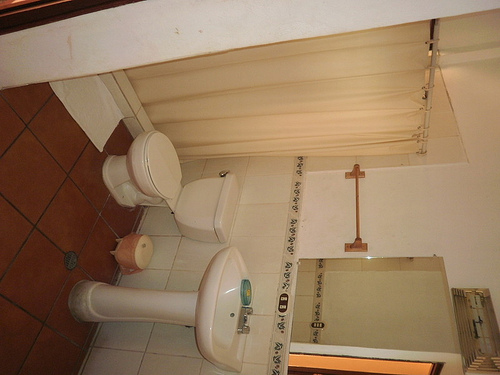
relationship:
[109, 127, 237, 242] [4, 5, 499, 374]
toilet in bathroom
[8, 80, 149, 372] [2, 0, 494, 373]
tiled floor of room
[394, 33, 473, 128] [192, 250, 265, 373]
light above sink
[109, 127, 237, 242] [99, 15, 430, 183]
toilet by shower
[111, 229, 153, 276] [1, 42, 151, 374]
basket on floor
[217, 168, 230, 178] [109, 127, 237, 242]
handle of toilet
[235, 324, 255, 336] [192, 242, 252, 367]
handle of sink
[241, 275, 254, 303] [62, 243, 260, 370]
item on sink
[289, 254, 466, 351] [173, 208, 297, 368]
mirror above sink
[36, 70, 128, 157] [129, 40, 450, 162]
towel outside shower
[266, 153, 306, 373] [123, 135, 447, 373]
trim on wall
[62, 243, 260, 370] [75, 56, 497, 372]
sink against wall